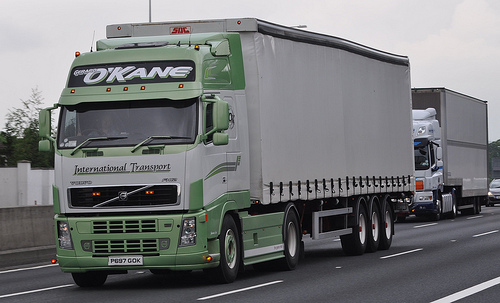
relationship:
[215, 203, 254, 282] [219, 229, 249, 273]
tire with rim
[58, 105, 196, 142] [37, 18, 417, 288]
windshield of semi truck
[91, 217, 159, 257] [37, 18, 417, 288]
grille of semi truck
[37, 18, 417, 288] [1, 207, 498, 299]
semi truck driving down street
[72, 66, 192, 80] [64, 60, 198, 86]
letters on back ground